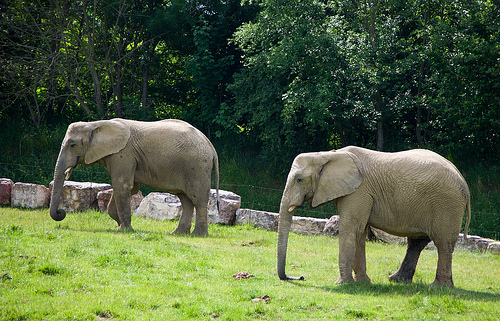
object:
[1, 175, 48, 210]
large rocks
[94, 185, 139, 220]
stone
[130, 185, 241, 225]
stone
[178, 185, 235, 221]
stone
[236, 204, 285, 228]
stone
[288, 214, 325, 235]
stone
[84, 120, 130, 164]
ear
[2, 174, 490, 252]
wall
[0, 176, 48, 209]
stone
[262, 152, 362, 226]
head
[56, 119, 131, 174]
head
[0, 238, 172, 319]
grassy field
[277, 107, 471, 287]
elephant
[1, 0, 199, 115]
tree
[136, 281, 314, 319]
grass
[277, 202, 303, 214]
tusk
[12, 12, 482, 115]
trees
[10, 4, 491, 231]
background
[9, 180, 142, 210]
rocks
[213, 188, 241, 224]
rocks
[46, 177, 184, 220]
rocks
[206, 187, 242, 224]
rocks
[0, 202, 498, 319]
field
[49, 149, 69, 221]
elephant trunks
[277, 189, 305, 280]
elephant trunks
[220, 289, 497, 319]
ground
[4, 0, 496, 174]
trees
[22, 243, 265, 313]
grass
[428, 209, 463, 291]
legs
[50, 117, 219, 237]
elephant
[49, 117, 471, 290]
elephants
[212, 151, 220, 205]
tail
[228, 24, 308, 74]
leaves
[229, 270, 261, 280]
droppings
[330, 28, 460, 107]
leaves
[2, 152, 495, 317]
field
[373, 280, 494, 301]
shadow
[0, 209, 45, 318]
ground